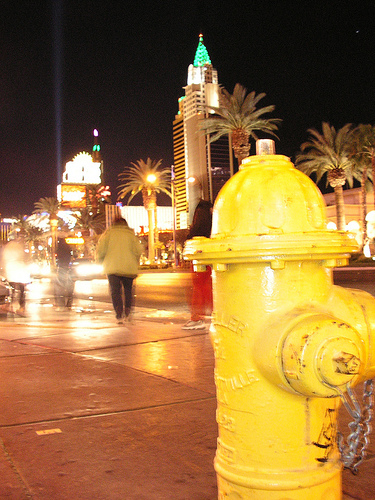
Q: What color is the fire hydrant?
A: Yellow.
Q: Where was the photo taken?
A: Las Vegas.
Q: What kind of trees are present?
A: Palm.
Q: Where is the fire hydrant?
A: On the sidewalk.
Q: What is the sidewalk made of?
A: Concrete.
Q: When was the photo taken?
A: In the evening.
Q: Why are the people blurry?
A: Not in focus.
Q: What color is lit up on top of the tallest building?
A: Green.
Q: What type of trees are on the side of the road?
A: Palm trees.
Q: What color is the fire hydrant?
A: Yellow.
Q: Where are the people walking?
A: Sidewalk.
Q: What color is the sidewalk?
A: Brown.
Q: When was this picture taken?
A: At night.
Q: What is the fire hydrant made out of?
A: Metal.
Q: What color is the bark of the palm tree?
A: Brown.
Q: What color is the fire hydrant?
A: Yellow.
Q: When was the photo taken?
A: At night.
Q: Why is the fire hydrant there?
A: To stop fires.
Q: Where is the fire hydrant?
A: Yellow.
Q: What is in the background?
A: Buildings.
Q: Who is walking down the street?
A: A woman.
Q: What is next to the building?
A: A palm tree.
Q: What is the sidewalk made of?
A: Concrete.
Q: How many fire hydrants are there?
A: One.